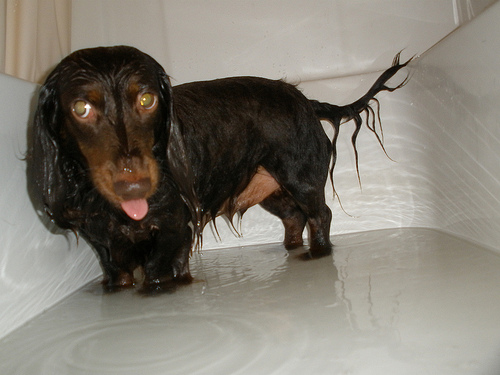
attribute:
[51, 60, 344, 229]
dog — wet  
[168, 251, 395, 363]
water — clouded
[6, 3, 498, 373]
dog — wet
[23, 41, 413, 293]
dog — wet, small, black and brown, soaked , black